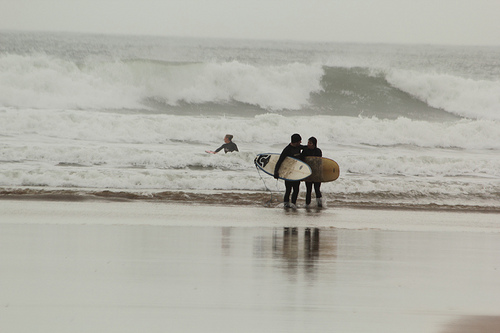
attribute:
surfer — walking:
[273, 130, 306, 210]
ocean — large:
[1, 30, 499, 235]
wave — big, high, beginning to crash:
[2, 51, 499, 122]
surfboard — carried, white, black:
[249, 152, 311, 181]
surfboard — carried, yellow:
[299, 152, 340, 183]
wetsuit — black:
[273, 142, 305, 204]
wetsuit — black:
[300, 145, 323, 205]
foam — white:
[2, 52, 499, 116]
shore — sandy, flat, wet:
[1, 196, 499, 331]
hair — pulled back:
[224, 132, 237, 139]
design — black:
[255, 154, 273, 170]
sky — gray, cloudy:
[3, 2, 498, 52]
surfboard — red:
[203, 147, 222, 157]